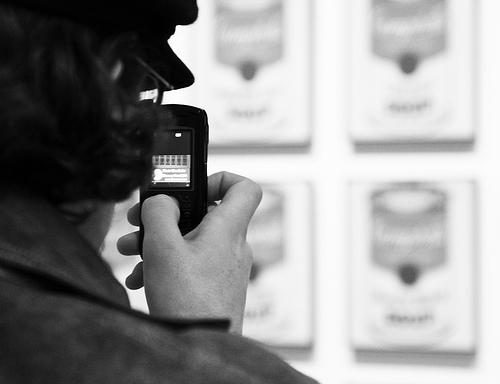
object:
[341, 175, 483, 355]
art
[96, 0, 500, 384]
wall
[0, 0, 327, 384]
person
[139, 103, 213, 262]
phone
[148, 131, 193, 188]
picture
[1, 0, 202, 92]
hat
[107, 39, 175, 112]
glasses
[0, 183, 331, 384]
jacket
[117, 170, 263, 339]
hand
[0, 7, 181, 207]
hair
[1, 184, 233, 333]
collar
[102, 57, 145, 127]
ear